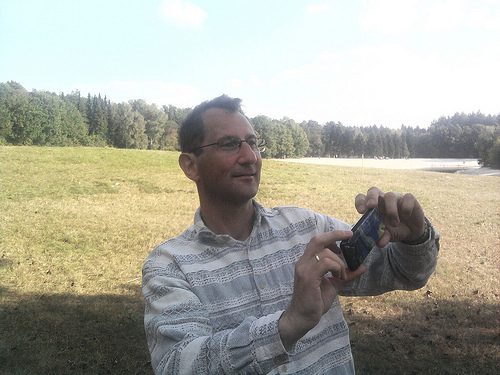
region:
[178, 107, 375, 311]
This is a picture of a man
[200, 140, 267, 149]
These are glasses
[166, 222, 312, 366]
This is a long sleeved shirt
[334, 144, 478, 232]
This is a lake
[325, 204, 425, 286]
This is a phone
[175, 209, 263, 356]
The shirt is white and grey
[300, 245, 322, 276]
This is a wedding band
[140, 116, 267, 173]
The hair is brown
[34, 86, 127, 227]
These are pine trees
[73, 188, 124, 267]
This is very dry grass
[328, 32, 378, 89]
part of a cloud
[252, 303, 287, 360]
edge of a sleeve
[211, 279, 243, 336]
part of a shirt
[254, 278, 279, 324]
part of a button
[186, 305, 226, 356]
part of a shirt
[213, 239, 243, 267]
part of a collar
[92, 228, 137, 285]
part of a ground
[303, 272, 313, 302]
part of a hanmd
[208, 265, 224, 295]
aprt fo a shirt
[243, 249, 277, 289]
part of a button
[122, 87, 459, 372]
man holding camera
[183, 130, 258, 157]
glasses of man standing in field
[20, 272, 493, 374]
shadows on field behind man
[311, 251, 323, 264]
ring on man's hand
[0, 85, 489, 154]
line of trees around field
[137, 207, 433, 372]
striped shirt of man hold camera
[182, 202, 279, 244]
collar of man's shirt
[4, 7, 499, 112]
bright sky above tree line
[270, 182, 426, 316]
man's hands holding camera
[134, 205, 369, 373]
gray and white striped shirt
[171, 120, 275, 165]
Black framed galsses on face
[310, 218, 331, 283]
Silver colored ring on finder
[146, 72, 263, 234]
man with brown hair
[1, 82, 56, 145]
Bright green tall trees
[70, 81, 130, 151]
Bright green tall trees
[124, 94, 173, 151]
Bright green tall trees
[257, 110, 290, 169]
Bright green tall trees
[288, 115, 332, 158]
Bright green tall trees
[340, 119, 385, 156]
Bright green tall trees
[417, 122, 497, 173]
Bright green tall trees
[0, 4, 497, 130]
clouds in blue sky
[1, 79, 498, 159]
line of trees on horizon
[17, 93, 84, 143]
green leaves on tree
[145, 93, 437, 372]
man with phone in hands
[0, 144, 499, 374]
field of green grass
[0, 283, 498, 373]
shadow on green grass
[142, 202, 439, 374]
white and gray shirt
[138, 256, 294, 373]
long sleeve on arm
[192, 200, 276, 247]
open collar of shirt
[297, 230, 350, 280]
finger with metal ring